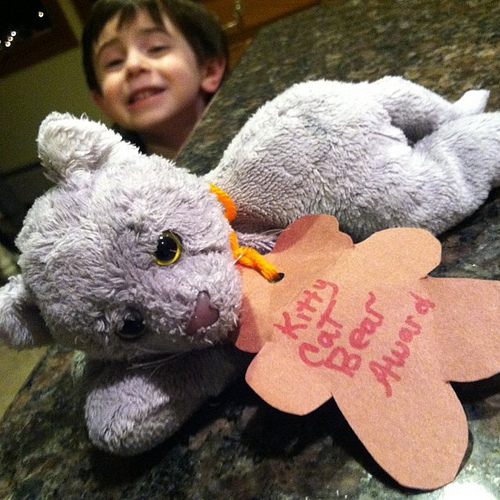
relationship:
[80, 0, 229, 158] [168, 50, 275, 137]
boy in background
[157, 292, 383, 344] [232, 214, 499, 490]
kitty written on note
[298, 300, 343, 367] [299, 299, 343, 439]
cat written on paper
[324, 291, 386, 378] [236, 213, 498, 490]
bear written on paper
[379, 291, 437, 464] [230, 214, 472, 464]
award written on paper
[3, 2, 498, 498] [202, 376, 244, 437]
countertop where stuffed animal sitting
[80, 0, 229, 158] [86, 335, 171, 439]
boy looking at teddy bear on countertop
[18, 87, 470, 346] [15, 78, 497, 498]
animal on tabletop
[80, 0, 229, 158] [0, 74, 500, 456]
boy has animal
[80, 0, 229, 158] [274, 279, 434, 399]
boy has award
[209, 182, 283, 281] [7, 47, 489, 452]
string on award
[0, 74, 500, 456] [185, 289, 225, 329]
animal has nose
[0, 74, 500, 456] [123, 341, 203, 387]
animal has whiskers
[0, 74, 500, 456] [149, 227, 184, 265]
animal has eye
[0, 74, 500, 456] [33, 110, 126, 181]
animal has ear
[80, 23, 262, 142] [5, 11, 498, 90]
boy on background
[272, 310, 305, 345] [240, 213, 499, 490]
letter on note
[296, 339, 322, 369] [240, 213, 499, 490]
letter on note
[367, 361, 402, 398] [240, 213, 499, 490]
letter on note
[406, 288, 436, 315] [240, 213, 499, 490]
letter on note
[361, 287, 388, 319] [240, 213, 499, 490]
letter on note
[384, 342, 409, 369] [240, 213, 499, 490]
letter on note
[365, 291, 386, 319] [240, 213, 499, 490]
letter on note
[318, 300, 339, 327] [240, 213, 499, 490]
letter on note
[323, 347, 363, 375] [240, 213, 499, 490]
letter on note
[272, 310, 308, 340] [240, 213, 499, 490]
letter on note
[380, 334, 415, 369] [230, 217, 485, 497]
letter on note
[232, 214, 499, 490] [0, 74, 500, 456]
note on animal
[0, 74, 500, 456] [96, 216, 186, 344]
animal has eyes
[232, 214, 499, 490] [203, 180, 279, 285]
note has string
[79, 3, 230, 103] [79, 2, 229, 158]
hair on boy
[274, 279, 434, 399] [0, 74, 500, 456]
award for animal